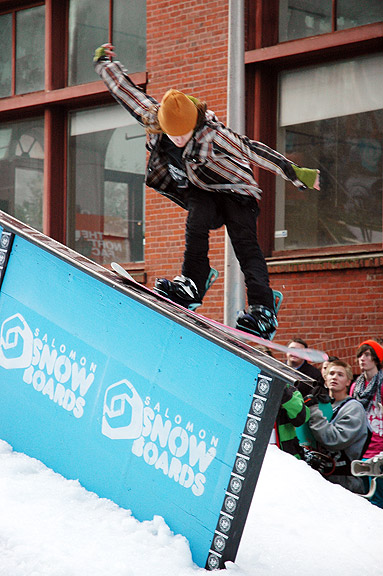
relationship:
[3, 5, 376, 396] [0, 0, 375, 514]
wall on side of buiding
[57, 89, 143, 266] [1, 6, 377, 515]
window on building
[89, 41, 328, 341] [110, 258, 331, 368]
boy on snowboard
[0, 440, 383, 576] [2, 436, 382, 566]
ground on ground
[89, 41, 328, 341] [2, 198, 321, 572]
boy next to ramp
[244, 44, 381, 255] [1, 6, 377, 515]
window on building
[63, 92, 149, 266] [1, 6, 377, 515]
window on building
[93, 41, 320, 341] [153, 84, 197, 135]
boy wear hat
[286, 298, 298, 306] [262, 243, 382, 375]
brick on wall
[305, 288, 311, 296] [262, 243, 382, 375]
brick on wall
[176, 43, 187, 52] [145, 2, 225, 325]
brick in wall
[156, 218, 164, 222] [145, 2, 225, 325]
brick in wall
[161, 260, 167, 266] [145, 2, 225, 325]
brick in wall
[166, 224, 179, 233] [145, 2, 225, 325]
brick in wall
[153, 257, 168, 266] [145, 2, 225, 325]
brick in wall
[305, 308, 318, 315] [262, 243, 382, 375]
brick in wall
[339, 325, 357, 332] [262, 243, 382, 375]
brick in wall